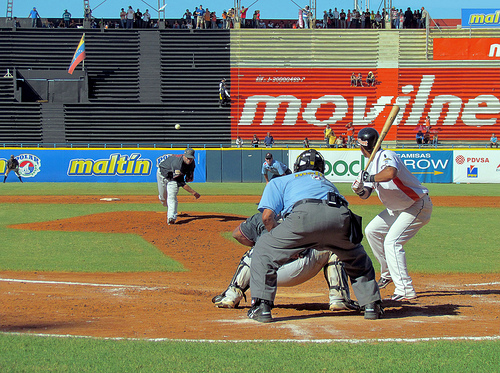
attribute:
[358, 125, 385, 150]
helmet — blue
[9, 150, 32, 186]
outfielder — waiting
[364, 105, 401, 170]
bat — wooden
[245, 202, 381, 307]
pant — gray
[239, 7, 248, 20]
shirt — blue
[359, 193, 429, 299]
pants — white, gray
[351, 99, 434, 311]
man — standing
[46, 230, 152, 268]
grass — green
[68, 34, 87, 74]
flag — yellow, blue and red, blowing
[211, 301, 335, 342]
chalk — smudged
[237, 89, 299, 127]
letter — white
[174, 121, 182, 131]
ball — mid air